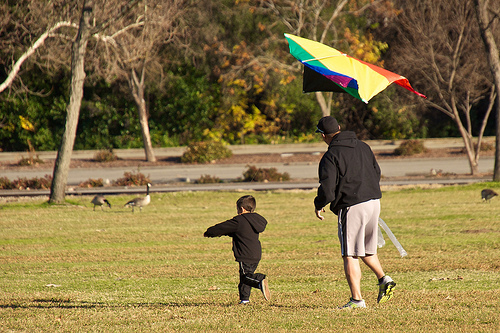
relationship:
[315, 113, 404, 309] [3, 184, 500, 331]
man walking on grass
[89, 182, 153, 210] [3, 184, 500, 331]
geese are on grass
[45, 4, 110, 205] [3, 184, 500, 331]
tree trunk in grass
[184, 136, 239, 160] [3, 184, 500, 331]
bush behind grass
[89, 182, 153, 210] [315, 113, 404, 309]
geese behind man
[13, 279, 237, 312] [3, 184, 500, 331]
shadow on grass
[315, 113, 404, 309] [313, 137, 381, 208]
man wearing hoodie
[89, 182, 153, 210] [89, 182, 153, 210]
geese and geese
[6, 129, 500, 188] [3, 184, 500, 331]
street behind grass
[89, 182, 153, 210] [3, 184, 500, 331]
geese on grass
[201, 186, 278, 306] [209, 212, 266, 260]
little boy wearing a sweatshirt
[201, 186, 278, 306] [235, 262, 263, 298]
little boy wearing pants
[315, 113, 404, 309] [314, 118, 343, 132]
man wearing a hat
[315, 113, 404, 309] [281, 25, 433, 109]
man flying a kite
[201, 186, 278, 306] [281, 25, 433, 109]
little boy flying a kite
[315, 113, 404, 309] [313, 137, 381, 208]
man wearing a hoodie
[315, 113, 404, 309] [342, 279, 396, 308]
man wearing sneakers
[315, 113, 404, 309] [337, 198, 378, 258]
man wearing shorts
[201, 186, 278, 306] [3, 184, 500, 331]
little boy running on grass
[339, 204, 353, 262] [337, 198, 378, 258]
line on shorts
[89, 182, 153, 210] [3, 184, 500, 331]
geese pecking grass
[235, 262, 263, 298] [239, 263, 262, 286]
pants with a line